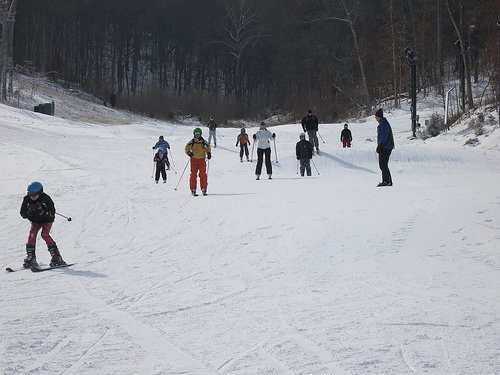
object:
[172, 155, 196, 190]
ski pole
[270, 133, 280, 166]
ski pole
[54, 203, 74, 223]
ski pole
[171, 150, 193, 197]
ski pole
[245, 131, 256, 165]
ski pole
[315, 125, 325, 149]
ski pole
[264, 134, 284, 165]
pole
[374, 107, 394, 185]
man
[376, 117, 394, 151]
jacket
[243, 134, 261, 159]
poles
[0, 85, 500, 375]
snow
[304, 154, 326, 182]
ski pole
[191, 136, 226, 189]
skier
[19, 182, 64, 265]
person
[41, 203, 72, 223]
pole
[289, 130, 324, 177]
person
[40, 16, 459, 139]
forest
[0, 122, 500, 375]
field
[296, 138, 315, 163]
jacket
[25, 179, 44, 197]
helmet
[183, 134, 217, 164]
coat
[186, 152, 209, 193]
pants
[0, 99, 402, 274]
people